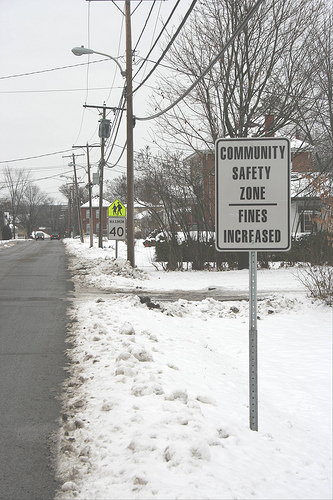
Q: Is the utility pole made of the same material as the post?
A: No, the utility pole is made of wood and the post is made of metal.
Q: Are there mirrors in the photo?
A: No, there are no mirrors.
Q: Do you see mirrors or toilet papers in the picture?
A: No, there are no mirrors or toilet papers.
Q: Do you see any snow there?
A: Yes, there is snow.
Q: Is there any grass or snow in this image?
A: Yes, there is snow.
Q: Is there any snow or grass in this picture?
A: Yes, there is snow.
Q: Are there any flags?
A: No, there are no flags.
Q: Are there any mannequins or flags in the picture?
A: No, there are no flags or mannequins.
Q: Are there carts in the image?
A: No, there are no carts.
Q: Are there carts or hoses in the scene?
A: No, there are no carts or hoses.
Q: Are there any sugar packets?
A: No, there are no sugar packets.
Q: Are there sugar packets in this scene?
A: No, there are no sugar packets.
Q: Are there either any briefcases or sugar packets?
A: No, there are no sugar packets or briefcases.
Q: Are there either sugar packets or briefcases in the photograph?
A: No, there are no sugar packets or briefcases.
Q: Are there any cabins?
A: No, there are no cabins.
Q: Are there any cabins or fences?
A: No, there are no cabins or fences.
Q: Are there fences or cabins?
A: No, there are no cabins or fences.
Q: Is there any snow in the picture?
A: Yes, there is snow.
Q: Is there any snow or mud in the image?
A: Yes, there is snow.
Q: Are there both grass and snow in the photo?
A: No, there is snow but no grass.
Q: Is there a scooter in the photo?
A: No, there are no scooters.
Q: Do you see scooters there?
A: No, there are no scooters.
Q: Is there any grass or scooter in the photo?
A: No, there are no scooters or grass.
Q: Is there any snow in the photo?
A: Yes, there is snow.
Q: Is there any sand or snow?
A: Yes, there is snow.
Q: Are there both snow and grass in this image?
A: No, there is snow but no grass.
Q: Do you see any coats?
A: No, there are no coats.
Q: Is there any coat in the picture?
A: No, there are no coats.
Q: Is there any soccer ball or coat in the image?
A: No, there are no coats or soccer balls.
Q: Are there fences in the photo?
A: No, there are no fences.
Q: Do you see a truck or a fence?
A: No, there are no fences or trucks.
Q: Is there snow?
A: Yes, there is snow.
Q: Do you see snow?
A: Yes, there is snow.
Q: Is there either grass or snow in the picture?
A: Yes, there is snow.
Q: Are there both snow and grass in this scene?
A: No, there is snow but no grass.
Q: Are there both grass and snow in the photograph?
A: No, there is snow but no grass.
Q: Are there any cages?
A: No, there are no cages.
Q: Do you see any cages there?
A: No, there are no cages.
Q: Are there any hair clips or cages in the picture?
A: No, there are no cages or hair clips.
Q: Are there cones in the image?
A: No, there are no cones.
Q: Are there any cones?
A: No, there are no cones.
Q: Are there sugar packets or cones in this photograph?
A: No, there are no cones or sugar packets.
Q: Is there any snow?
A: Yes, there is snow.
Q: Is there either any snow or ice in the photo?
A: Yes, there is snow.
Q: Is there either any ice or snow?
A: Yes, there is snow.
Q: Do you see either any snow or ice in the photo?
A: Yes, there is snow.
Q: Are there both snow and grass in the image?
A: No, there is snow but no grass.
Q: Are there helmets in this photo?
A: No, there are no helmets.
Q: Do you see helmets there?
A: No, there are no helmets.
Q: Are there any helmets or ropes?
A: No, there are no helmets or ropes.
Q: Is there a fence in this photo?
A: No, there are no fences.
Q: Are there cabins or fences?
A: No, there are no fences or cabins.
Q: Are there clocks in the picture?
A: No, there are no clocks.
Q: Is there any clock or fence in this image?
A: No, there are no clocks or fences.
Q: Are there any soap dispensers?
A: No, there are no soap dispensers.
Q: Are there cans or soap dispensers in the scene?
A: No, there are no soap dispensers or cans.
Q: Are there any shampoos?
A: No, there are no shampoos.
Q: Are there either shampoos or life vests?
A: No, there are no shampoos or life vests.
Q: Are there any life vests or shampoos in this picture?
A: No, there are no shampoos or life vests.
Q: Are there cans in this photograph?
A: No, there are no cans.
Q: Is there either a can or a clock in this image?
A: No, there are no cans or clocks.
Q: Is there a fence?
A: No, there are no fences.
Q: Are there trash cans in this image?
A: No, there are no trash cans.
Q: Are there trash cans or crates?
A: No, there are no trash cans or crates.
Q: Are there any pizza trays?
A: No, there are no pizza trays.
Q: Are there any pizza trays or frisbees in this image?
A: No, there are no pizza trays or frisbees.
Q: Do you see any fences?
A: No, there are no fences.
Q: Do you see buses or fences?
A: No, there are no fences or buses.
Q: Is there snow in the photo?
A: Yes, there is snow.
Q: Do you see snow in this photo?
A: Yes, there is snow.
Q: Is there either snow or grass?
A: Yes, there is snow.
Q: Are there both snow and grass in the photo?
A: No, there is snow but no grass.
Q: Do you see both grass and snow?
A: No, there is snow but no grass.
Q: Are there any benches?
A: No, there are no benches.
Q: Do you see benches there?
A: No, there are no benches.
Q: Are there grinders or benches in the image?
A: No, there are no benches or grinders.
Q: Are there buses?
A: No, there are no buses.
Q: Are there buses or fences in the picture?
A: No, there are no buses or fences.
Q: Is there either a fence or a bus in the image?
A: No, there are no buses or fences.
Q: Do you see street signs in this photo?
A: Yes, there is a street sign.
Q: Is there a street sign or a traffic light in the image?
A: Yes, there is a street sign.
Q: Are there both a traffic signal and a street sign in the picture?
A: No, there is a street sign but no traffic lights.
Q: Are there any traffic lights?
A: No, there are no traffic lights.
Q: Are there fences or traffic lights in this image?
A: No, there are no traffic lights or fences.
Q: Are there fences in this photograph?
A: No, there are no fences.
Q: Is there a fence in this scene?
A: No, there are no fences.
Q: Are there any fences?
A: No, there are no fences.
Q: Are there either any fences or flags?
A: No, there are no fences or flags.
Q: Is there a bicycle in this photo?
A: No, there are no bicycles.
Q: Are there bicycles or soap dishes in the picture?
A: No, there are no bicycles or soap dishes.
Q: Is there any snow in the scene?
A: Yes, there is snow.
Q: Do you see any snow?
A: Yes, there is snow.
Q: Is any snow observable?
A: Yes, there is snow.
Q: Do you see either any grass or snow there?
A: Yes, there is snow.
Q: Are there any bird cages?
A: No, there are no bird cages.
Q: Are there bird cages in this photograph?
A: No, there are no bird cages.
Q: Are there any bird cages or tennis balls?
A: No, there are no bird cages or tennis balls.